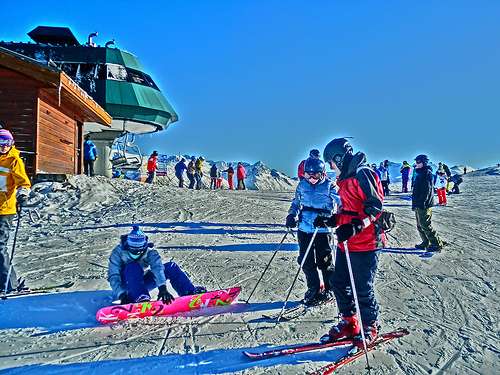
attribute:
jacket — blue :
[287, 179, 338, 234]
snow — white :
[286, 260, 495, 374]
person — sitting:
[111, 227, 204, 298]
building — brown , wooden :
[21, 64, 163, 188]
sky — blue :
[1, 0, 499, 195]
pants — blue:
[115, 262, 235, 321]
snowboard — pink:
[99, 279, 239, 330]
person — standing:
[408, 153, 445, 250]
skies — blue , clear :
[275, 25, 442, 122]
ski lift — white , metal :
[108, 134, 141, 173]